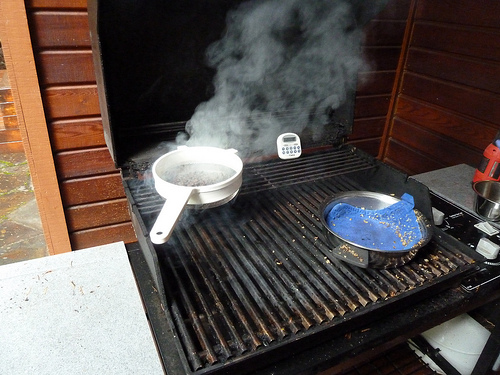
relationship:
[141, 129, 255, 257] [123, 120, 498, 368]
bowl on grill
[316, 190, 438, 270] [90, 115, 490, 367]
bowl on grill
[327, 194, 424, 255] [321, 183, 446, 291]
blue item on pot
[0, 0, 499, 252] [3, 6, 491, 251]
wall on side of building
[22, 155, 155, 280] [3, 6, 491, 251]
wall on side of building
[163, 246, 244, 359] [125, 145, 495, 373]
metal rail on grill